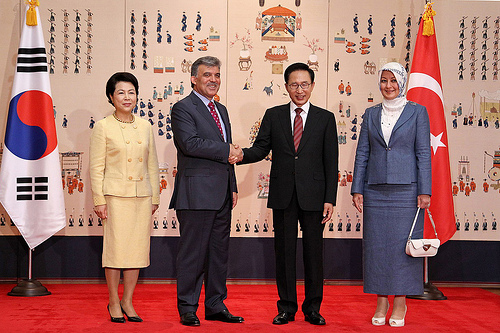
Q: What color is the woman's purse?
A: White.